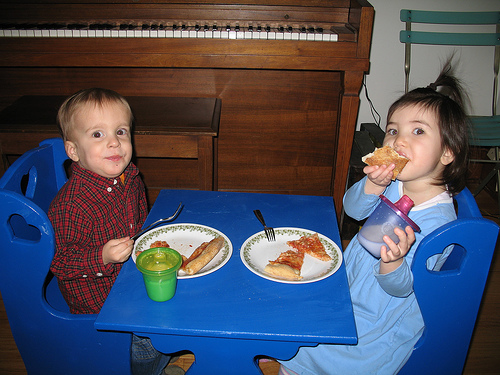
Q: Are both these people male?
A: No, they are both male and female.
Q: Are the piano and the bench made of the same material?
A: Yes, both the piano and the bench are made of wood.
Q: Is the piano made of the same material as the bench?
A: Yes, both the piano and the bench are made of wood.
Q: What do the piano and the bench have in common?
A: The material, both the piano and the bench are wooden.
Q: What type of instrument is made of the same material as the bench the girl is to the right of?
A: The piano is made of the same material as the bench.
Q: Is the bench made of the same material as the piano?
A: Yes, both the bench and the piano are made of wood.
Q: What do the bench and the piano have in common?
A: The material, both the bench and the piano are wooden.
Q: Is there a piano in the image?
A: Yes, there is a piano.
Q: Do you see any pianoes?
A: Yes, there is a piano.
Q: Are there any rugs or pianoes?
A: Yes, there is a piano.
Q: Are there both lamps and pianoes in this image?
A: No, there is a piano but no lamps.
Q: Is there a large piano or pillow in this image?
A: Yes, there is a large piano.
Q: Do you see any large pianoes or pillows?
A: Yes, there is a large piano.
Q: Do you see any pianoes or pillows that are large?
A: Yes, the piano is large.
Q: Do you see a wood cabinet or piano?
A: Yes, there is a wood piano.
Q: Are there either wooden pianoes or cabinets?
A: Yes, there is a wood piano.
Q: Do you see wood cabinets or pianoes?
A: Yes, there is a wood piano.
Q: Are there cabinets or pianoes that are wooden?
A: Yes, the piano is wooden.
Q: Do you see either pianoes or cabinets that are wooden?
A: Yes, the piano is wooden.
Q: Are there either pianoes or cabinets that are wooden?
A: Yes, the piano is wooden.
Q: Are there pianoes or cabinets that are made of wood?
A: Yes, the piano is made of wood.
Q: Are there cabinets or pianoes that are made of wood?
A: Yes, the piano is made of wood.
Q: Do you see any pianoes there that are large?
A: Yes, there is a large piano.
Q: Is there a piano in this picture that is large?
A: Yes, there is a piano that is large.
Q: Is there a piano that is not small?
A: Yes, there is a large piano.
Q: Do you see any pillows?
A: No, there are no pillows.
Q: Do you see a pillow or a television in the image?
A: No, there are no pillows or televisions.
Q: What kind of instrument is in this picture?
A: The instrument is a piano.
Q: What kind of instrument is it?
A: The instrument is a piano.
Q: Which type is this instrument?
A: This is a piano.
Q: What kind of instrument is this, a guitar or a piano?
A: This is a piano.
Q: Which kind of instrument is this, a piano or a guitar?
A: This is a piano.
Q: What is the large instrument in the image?
A: The instrument is a piano.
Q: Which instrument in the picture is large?
A: The instrument is a piano.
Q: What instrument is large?
A: The instrument is a piano.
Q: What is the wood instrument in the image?
A: The instrument is a piano.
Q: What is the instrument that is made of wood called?
A: The instrument is a piano.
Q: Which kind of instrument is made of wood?
A: The instrument is a piano.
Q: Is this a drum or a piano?
A: This is a piano.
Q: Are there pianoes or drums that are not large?
A: No, there is a piano but it is large.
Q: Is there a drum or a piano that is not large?
A: No, there is a piano but it is large.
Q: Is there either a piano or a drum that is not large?
A: No, there is a piano but it is large.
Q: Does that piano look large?
A: Yes, the piano is large.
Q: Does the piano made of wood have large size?
A: Yes, the piano is large.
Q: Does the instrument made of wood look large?
A: Yes, the piano is large.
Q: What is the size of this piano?
A: The piano is large.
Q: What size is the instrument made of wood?
A: The piano is large.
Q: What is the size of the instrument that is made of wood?
A: The piano is large.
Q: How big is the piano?
A: The piano is large.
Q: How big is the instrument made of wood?
A: The piano is large.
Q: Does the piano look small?
A: No, the piano is large.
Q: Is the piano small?
A: No, the piano is large.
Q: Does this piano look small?
A: No, the piano is large.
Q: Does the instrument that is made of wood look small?
A: No, the piano is large.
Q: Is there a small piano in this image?
A: No, there is a piano but it is large.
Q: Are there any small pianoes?
A: No, there is a piano but it is large.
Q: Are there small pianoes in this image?
A: No, there is a piano but it is large.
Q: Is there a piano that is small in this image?
A: No, there is a piano but it is large.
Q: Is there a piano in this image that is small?
A: No, there is a piano but it is large.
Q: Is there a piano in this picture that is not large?
A: No, there is a piano but it is large.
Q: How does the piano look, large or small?
A: The piano is large.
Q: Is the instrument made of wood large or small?
A: The piano is large.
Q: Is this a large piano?
A: Yes, this is a large piano.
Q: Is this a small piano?
A: No, this is a large piano.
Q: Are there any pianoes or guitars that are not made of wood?
A: No, there is a piano but it is made of wood.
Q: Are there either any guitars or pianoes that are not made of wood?
A: No, there is a piano but it is made of wood.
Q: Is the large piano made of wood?
A: Yes, the piano is made of wood.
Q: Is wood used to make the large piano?
A: Yes, the piano is made of wood.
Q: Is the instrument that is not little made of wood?
A: Yes, the piano is made of wood.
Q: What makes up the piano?
A: The piano is made of wood.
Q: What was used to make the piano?
A: The piano is made of wood.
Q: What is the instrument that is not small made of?
A: The piano is made of wood.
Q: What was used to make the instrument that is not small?
A: The piano is made of wood.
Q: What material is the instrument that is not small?
A: The piano is made of wood.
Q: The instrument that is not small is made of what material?
A: The piano is made of wood.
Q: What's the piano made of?
A: The piano is made of wood.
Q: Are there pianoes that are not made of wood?
A: No, there is a piano but it is made of wood.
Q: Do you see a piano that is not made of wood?
A: No, there is a piano but it is made of wood.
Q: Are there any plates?
A: Yes, there is a plate.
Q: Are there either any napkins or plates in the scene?
A: Yes, there is a plate.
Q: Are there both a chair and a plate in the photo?
A: Yes, there are both a plate and a chair.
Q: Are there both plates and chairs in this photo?
A: Yes, there are both a plate and a chair.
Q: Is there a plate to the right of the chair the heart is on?
A: Yes, there is a plate to the right of the chair.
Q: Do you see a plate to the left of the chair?
A: No, the plate is to the right of the chair.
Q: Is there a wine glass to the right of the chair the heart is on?
A: No, there is a plate to the right of the chair.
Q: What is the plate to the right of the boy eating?
A: The plate is eating a pizza.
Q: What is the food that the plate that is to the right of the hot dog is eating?
A: The food is a pizza.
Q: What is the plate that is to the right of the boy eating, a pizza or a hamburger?
A: The plate is eating a pizza.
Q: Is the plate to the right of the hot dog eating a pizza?
A: Yes, the plate is eating a pizza.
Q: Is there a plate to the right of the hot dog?
A: Yes, there is a plate to the right of the hot dog.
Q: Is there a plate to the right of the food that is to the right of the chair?
A: Yes, there is a plate to the right of the hot dog.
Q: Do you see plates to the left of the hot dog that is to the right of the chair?
A: No, the plate is to the right of the hot dog.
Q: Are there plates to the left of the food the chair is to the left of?
A: No, the plate is to the right of the hot dog.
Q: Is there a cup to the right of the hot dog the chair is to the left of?
A: No, there is a plate to the right of the hot dog.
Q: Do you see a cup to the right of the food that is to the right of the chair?
A: No, there is a plate to the right of the hot dog.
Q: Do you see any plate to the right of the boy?
A: Yes, there is a plate to the right of the boy.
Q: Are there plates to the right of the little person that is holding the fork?
A: Yes, there is a plate to the right of the boy.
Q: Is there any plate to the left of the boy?
A: No, the plate is to the right of the boy.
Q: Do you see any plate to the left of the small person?
A: No, the plate is to the right of the boy.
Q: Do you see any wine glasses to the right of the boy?
A: No, there is a plate to the right of the boy.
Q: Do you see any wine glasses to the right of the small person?
A: No, there is a plate to the right of the boy.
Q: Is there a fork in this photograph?
A: Yes, there is a fork.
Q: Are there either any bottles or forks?
A: Yes, there is a fork.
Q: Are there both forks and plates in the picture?
A: Yes, there are both a fork and a plate.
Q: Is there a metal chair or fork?
A: Yes, there is a metal fork.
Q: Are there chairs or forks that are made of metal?
A: Yes, the fork is made of metal.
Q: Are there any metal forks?
A: Yes, there is a metal fork.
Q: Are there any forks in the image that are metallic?
A: Yes, there is a fork that is metallic.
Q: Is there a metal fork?
A: Yes, there is a fork that is made of metal.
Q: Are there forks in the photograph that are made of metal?
A: Yes, there is a fork that is made of metal.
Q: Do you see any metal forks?
A: Yes, there is a fork that is made of metal.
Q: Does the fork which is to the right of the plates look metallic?
A: Yes, the fork is metallic.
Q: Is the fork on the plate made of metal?
A: Yes, the fork is made of metal.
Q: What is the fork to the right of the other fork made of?
A: The fork is made of metal.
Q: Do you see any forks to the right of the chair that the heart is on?
A: Yes, there is a fork to the right of the chair.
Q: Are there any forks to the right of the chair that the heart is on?
A: Yes, there is a fork to the right of the chair.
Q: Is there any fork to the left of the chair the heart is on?
A: No, the fork is to the right of the chair.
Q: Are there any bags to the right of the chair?
A: No, there is a fork to the right of the chair.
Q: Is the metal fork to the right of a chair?
A: Yes, the fork is to the right of a chair.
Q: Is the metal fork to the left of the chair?
A: No, the fork is to the right of the chair.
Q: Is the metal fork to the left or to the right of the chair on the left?
A: The fork is to the right of the chair.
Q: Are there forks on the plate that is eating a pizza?
A: Yes, there is a fork on the plate.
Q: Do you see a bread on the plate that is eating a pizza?
A: No, there is a fork on the plate.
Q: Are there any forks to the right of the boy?
A: Yes, there is a fork to the right of the boy.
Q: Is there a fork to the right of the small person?
A: Yes, there is a fork to the right of the boy.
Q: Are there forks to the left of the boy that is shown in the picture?
A: No, the fork is to the right of the boy.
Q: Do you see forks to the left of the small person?
A: No, the fork is to the right of the boy.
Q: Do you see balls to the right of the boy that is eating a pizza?
A: No, there is a fork to the right of the boy.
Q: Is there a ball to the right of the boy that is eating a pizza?
A: No, there is a fork to the right of the boy.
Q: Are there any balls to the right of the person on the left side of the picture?
A: No, there is a fork to the right of the boy.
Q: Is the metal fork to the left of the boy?
A: No, the fork is to the right of the boy.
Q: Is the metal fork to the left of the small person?
A: No, the fork is to the right of the boy.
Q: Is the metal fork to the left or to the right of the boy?
A: The fork is to the right of the boy.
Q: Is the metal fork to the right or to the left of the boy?
A: The fork is to the right of the boy.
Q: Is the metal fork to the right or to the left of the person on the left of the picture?
A: The fork is to the right of the boy.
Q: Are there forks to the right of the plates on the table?
A: Yes, there is a fork to the right of the plates.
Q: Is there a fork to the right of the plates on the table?
A: Yes, there is a fork to the right of the plates.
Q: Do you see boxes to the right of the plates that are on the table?
A: No, there is a fork to the right of the plates.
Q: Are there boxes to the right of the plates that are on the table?
A: No, there is a fork to the right of the plates.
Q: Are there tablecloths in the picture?
A: No, there are no tablecloths.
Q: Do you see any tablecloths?
A: No, there are no tablecloths.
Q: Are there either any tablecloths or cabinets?
A: No, there are no tablecloths or cabinets.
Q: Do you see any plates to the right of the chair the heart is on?
A: Yes, there are plates to the right of the chair.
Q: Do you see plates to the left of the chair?
A: No, the plates are to the right of the chair.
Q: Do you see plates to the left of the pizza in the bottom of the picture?
A: Yes, there are plates to the left of the pizza.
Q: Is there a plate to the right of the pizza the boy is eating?
A: No, the plates are to the left of the pizza.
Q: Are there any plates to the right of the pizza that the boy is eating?
A: No, the plates are to the left of the pizza.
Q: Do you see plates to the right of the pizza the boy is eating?
A: No, the plates are to the left of the pizza.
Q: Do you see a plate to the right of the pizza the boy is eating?
A: No, the plates are to the left of the pizza.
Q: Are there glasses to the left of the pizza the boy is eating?
A: No, there are plates to the left of the pizza.